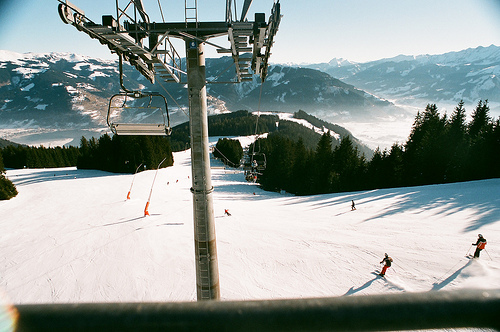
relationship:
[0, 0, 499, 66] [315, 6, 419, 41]
white clouds in blue sky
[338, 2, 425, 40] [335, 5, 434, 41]
white clouds in blue sky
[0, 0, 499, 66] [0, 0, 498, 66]
white clouds in blue sky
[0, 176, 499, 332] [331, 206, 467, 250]
snow on hill side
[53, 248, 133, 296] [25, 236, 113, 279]
snow on hill side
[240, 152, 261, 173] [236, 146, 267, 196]
person in ski lift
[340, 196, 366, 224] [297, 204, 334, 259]
person sliding down hill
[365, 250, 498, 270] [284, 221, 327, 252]
people skiing down slope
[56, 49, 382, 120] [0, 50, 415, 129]
hill in front of hill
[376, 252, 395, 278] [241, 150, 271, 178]
people on ski lift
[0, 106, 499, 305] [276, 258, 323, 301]
ice on ground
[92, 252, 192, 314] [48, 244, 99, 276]
ice on ground